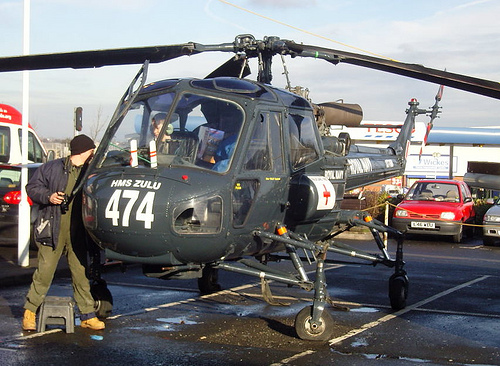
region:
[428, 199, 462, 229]
a headlight on the car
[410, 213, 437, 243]
a tag on the front of the car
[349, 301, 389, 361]
a white line on the ground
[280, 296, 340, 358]
a tire on the plane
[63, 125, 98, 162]
a mna wearing a hat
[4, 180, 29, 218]
a tail light on a car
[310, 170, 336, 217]
a symbol on the side on the plane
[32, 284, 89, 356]
a stool next to the man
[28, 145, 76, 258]
a man wearing a jacket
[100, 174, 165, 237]
White wording on helicopter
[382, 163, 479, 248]
Small black and red car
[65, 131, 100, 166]
Man with black hat on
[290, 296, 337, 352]
Flat tire on the helicopter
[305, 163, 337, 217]
Red and white emergency sign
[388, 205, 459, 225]
Two small headlights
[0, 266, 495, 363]
white lines in the road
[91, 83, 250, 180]
One large window on the helicopter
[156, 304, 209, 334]
black cement on ground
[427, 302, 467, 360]
black cement on ground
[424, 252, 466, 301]
black cement on ground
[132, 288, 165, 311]
black cement on ground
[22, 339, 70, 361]
black cement on ground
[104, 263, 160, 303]
black cement on ground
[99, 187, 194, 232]
white number on plane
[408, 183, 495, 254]
red paint on car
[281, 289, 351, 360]
black tire on plane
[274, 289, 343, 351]
the wheel of the helicopter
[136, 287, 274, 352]
wet puddles on the ground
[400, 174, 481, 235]
red car is parked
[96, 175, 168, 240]
474 is on the front of the helicopter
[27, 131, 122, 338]
man is working on the helicopter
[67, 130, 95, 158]
man is wearing a hat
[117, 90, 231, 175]
windshield of the helicopter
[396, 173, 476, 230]
this is a car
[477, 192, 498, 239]
this is a car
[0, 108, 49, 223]
this is a car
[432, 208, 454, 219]
headlights of a car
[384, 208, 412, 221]
headlights of a car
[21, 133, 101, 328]
that is a person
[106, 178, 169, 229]
writings on the plane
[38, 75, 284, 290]
front of the helicopter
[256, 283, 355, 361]
tire of the helicopter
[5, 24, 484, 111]
blades of the helicopter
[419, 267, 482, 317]
white line on ground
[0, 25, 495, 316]
helicopter parked in parking lot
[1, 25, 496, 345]
parked helicopter in parking lot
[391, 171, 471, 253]
small car parked in space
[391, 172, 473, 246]
parked car is small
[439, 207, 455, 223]
left headlight is on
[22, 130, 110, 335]
worker standing by ehlicopter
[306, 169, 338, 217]
medical symbol on helicopter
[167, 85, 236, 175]
A window on a vehicle.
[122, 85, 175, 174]
A window on a vehicle.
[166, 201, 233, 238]
A window on a vehicle.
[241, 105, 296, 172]
A window on a vehicle.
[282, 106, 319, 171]
A window on a vehicle.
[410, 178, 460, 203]
A window on a vehicle.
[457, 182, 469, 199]
A window on a vehicle.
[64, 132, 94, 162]
man wearing a black hat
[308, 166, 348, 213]
red cross sign on the helicopter